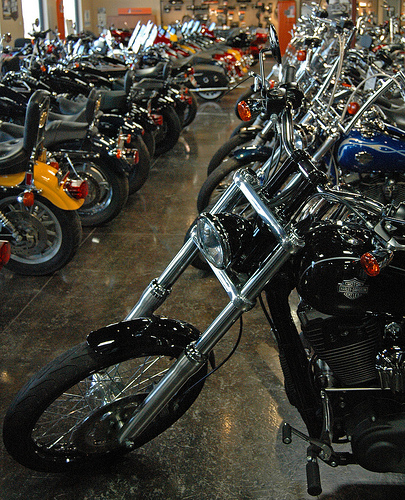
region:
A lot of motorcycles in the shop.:
[46, 28, 372, 266]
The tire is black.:
[41, 309, 239, 455]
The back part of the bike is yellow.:
[6, 153, 92, 264]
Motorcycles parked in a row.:
[268, 13, 369, 279]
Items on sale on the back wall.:
[168, 6, 284, 33]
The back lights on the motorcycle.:
[43, 171, 89, 212]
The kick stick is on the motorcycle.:
[273, 400, 345, 498]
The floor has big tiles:
[60, 258, 172, 334]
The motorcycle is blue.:
[332, 120, 400, 181]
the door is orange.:
[267, 6, 319, 67]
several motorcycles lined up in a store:
[12, 19, 392, 467]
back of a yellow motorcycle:
[0, 95, 85, 297]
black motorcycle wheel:
[1, 315, 222, 479]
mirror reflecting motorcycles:
[151, 7, 305, 121]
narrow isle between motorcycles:
[55, 85, 269, 327]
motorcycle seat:
[16, 84, 106, 146]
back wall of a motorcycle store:
[71, 2, 400, 57]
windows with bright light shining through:
[0, 3, 90, 45]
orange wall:
[268, 0, 306, 46]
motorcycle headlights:
[175, 195, 230, 293]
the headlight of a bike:
[185, 205, 233, 279]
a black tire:
[18, 308, 206, 486]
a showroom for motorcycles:
[4, 15, 396, 494]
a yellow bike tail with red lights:
[1, 142, 97, 223]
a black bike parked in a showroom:
[74, 133, 400, 498]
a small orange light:
[355, 240, 385, 290]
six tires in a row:
[4, 75, 200, 274]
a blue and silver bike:
[340, 122, 403, 171]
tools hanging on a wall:
[157, 2, 275, 40]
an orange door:
[274, 0, 306, 64]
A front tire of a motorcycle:
[26, 296, 201, 466]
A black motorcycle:
[84, 197, 402, 455]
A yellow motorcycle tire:
[0, 164, 76, 280]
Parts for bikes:
[153, 6, 272, 26]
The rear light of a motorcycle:
[54, 172, 103, 210]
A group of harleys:
[23, 39, 203, 110]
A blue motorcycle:
[327, 120, 402, 190]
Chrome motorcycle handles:
[307, 24, 400, 118]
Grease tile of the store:
[94, 242, 147, 292]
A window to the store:
[24, 9, 44, 41]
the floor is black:
[26, 265, 107, 353]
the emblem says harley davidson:
[319, 251, 386, 330]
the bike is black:
[72, 290, 185, 377]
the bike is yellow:
[18, 158, 96, 215]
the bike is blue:
[342, 114, 392, 157]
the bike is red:
[204, 49, 225, 69]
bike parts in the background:
[155, 4, 278, 39]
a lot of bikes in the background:
[37, 20, 294, 241]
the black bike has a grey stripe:
[292, 230, 385, 290]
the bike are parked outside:
[115, 55, 284, 258]